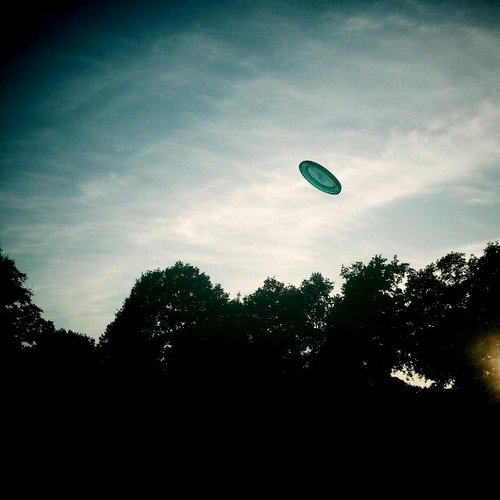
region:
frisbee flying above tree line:
[123, 113, 490, 328]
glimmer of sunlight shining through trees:
[479, 330, 498, 398]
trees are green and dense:
[21, 265, 496, 497]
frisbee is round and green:
[293, 155, 350, 197]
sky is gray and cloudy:
[168, 46, 490, 157]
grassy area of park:
[18, 403, 498, 498]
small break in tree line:
[388, 361, 462, 397]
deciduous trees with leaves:
[115, 258, 497, 391]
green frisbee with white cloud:
[281, 148, 353, 202]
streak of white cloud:
[178, 80, 499, 248]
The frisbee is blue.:
[294, 149, 344, 206]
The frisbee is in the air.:
[289, 151, 349, 200]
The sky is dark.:
[16, 15, 133, 126]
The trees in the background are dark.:
[121, 254, 235, 387]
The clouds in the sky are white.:
[369, 121, 498, 194]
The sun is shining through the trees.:
[466, 327, 496, 403]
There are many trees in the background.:
[110, 238, 497, 399]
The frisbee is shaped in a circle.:
[293, 151, 346, 207]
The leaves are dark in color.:
[126, 255, 225, 345]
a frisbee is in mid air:
[299, 158, 341, 196]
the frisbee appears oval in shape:
[302, 157, 340, 197]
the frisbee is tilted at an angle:
[297, 158, 342, 195]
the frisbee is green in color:
[297, 160, 340, 197]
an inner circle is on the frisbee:
[308, 163, 338, 190]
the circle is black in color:
[304, 164, 336, 192]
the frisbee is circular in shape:
[298, 155, 342, 195]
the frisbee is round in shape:
[297, 160, 341, 194]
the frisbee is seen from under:
[299, 156, 341, 196]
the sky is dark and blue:
[3, 2, 499, 302]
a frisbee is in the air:
[296, 158, 340, 198]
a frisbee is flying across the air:
[298, 158, 343, 202]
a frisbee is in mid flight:
[300, 158, 341, 197]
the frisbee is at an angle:
[299, 157, 341, 197]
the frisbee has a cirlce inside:
[306, 161, 338, 191]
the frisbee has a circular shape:
[298, 157, 341, 197]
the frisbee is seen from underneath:
[301, 158, 341, 199]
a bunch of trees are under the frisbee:
[1, 243, 498, 498]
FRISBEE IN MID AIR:
[297, 166, 359, 205]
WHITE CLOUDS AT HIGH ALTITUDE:
[62, 109, 157, 170]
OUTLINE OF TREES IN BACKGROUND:
[112, 241, 462, 405]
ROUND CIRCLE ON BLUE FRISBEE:
[307, 159, 340, 201]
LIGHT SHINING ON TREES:
[459, 336, 499, 366]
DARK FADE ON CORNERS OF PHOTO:
[4, 11, 134, 91]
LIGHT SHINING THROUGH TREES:
[359, 341, 480, 414]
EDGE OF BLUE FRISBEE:
[311, 181, 357, 207]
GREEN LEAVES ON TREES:
[252, 284, 302, 315]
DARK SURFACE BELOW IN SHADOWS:
[94, 409, 423, 497]